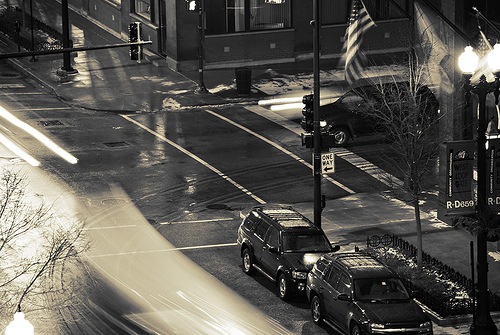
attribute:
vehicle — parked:
[226, 196, 347, 306]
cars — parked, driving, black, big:
[236, 186, 407, 329]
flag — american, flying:
[337, 2, 384, 82]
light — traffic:
[122, 23, 149, 59]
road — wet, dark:
[56, 83, 252, 217]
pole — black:
[20, 48, 71, 63]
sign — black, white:
[317, 151, 348, 180]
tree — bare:
[368, 74, 441, 236]